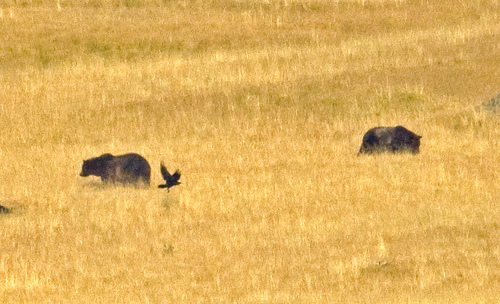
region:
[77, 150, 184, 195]
a bear and bird in a field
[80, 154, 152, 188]
a bear walking in a field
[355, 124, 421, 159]
a bear walking in a field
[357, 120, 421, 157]
back of a bear walking in a field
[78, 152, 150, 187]
side of a bear walking in a field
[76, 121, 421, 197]
two bears and a bird in a field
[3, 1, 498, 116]
a lush golden field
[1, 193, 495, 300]
a field of golden grass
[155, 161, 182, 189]
a small black bird in flight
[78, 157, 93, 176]
the head of a bear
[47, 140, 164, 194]
Bear in a field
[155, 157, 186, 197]
Bird flying over the field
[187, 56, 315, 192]
The field is dry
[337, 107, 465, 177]
The bear is looking at the ground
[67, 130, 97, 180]
Bear looking to the left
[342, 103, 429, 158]
The bear is dark colored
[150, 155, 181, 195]
The bird is black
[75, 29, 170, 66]
Clumps of green grass in the field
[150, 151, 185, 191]
The birds wings are outstretched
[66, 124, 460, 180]
Two bears in the field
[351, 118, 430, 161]
bison grazing in a field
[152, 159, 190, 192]
hawk swooping low over a field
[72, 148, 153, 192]
inept bear failing to hunt properly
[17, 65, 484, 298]
three animals in a dry grassy field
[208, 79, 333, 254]
light brown dry grassy field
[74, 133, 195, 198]
a hawk and bear in dry grass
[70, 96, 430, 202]
three creatures in the wild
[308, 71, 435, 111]
slightly green patch in dry field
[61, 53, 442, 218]
wildlife in natural habitat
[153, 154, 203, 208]
large raptor hunting in dry field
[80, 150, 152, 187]
a bear walking in grass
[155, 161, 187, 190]
a bird in flight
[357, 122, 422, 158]
a bear walking in grass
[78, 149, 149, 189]
the side of a bear walking in grass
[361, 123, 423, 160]
the back of a bear walking in grass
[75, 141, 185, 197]
a bear and a bird in a field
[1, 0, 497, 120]
a stretch of grassy land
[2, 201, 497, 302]
a golden field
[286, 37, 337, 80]
light spot in dry grass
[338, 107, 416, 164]
black bear walking east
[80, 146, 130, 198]
black bear heading west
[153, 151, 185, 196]
black bird flying east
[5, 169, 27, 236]
part of unknown black object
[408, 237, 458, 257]
grass is very dry looking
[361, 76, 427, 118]
green spot in brown grass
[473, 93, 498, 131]
part of unknown object in grass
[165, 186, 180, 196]
bird with thin legs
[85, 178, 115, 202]
shadow of black bear